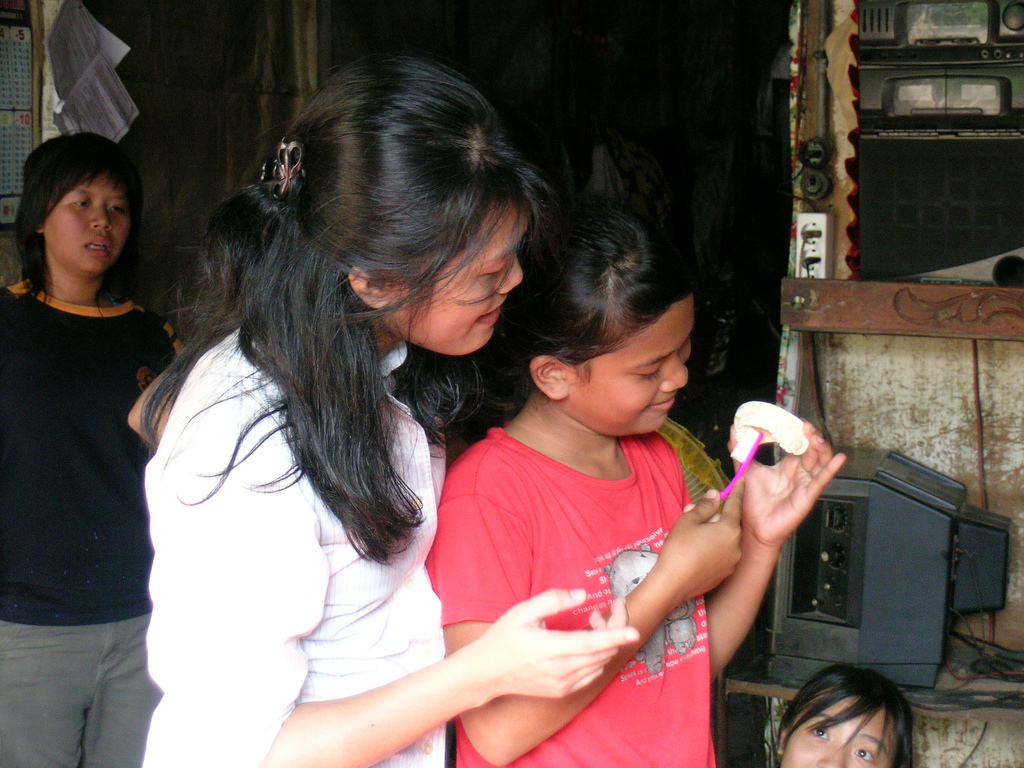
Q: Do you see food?
A: No, there is no food.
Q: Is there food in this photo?
A: No, there is no food.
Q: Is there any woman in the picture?
A: Yes, there is a woman.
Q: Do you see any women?
A: Yes, there is a woman.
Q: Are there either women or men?
A: Yes, there is a woman.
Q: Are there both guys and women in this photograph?
A: No, there is a woman but no guys.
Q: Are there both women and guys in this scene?
A: No, there is a woman but no guys.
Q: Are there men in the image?
A: No, there are no men.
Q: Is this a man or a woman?
A: This is a woman.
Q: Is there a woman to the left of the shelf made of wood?
A: Yes, there is a woman to the left of the shelf.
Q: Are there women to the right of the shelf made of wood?
A: No, the woman is to the left of the shelf.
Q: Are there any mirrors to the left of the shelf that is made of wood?
A: No, there is a woman to the left of the shelf.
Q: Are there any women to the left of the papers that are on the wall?
A: No, the woman is to the right of the papers.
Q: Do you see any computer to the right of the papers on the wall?
A: No, there is a woman to the right of the papers.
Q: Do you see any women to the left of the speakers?
A: Yes, there is a woman to the left of the speakers.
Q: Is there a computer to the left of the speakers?
A: No, there is a woman to the left of the speakers.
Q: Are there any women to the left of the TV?
A: Yes, there is a woman to the left of the TV.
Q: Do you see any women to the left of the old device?
A: Yes, there is a woman to the left of the TV.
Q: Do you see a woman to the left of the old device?
A: Yes, there is a woman to the left of the TV.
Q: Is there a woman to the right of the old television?
A: No, the woman is to the left of the TV.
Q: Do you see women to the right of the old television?
A: No, the woman is to the left of the TV.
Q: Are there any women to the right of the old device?
A: No, the woman is to the left of the TV.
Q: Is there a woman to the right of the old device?
A: No, the woman is to the left of the TV.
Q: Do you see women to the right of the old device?
A: No, the woman is to the left of the TV.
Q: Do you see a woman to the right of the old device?
A: No, the woman is to the left of the TV.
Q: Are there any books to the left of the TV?
A: No, there is a woman to the left of the TV.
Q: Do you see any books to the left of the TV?
A: No, there is a woman to the left of the TV.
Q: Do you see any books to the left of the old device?
A: No, there is a woman to the left of the TV.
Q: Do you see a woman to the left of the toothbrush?
A: Yes, there is a woman to the left of the toothbrush.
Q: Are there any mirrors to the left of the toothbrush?
A: No, there is a woman to the left of the toothbrush.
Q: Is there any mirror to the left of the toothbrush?
A: No, there is a woman to the left of the toothbrush.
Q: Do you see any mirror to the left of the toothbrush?
A: No, there is a woman to the left of the toothbrush.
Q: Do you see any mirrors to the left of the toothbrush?
A: No, there is a woman to the left of the toothbrush.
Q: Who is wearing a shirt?
A: The woman is wearing a shirt.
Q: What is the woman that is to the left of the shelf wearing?
A: The woman is wearing a shirt.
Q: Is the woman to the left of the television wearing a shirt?
A: Yes, the woman is wearing a shirt.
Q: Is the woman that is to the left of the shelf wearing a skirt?
A: No, the woman is wearing a shirt.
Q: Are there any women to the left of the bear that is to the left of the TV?
A: Yes, there is a woman to the left of the bear.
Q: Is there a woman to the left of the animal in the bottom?
A: Yes, there is a woman to the left of the bear.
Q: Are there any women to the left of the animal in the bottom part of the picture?
A: Yes, there is a woman to the left of the bear.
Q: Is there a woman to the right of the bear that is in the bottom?
A: No, the woman is to the left of the bear.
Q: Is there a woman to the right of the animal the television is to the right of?
A: No, the woman is to the left of the bear.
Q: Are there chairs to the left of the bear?
A: No, there is a woman to the left of the bear.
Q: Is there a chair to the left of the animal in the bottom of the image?
A: No, there is a woman to the left of the bear.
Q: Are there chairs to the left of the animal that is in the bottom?
A: No, there is a woman to the left of the bear.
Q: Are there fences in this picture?
A: No, there are no fences.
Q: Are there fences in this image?
A: No, there are no fences.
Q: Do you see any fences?
A: No, there are no fences.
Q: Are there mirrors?
A: No, there are no mirrors.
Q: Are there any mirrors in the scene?
A: No, there are no mirrors.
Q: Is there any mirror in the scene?
A: No, there are no mirrors.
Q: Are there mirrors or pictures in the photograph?
A: No, there are no mirrors or pictures.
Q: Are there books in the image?
A: No, there are no books.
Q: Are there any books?
A: No, there are no books.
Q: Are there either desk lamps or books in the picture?
A: No, there are no books or desk lamps.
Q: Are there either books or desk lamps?
A: No, there are no books or desk lamps.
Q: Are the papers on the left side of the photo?
A: Yes, the papers are on the left of the image.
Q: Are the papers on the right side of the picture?
A: No, the papers are on the left of the image.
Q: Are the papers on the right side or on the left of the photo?
A: The papers are on the left of the image.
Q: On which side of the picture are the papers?
A: The papers are on the left of the image.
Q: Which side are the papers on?
A: The papers are on the left of the image.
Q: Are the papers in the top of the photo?
A: Yes, the papers are in the top of the image.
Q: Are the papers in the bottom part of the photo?
A: No, the papers are in the top of the image.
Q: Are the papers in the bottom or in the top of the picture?
A: The papers are in the top of the image.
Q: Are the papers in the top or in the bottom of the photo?
A: The papers are in the top of the image.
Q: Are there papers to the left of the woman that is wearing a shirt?
A: Yes, there are papers to the left of the woman.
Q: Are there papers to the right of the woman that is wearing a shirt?
A: No, the papers are to the left of the woman.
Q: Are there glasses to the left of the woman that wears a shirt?
A: No, there are papers to the left of the woman.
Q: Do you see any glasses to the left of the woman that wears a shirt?
A: No, there are papers to the left of the woman.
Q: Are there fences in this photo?
A: No, there are no fences.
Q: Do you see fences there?
A: No, there are no fences.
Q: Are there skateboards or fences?
A: No, there are no fences or skateboards.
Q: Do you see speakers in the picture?
A: Yes, there are speakers.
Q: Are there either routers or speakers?
A: Yes, there are speakers.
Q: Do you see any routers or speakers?
A: Yes, there are speakers.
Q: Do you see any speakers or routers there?
A: Yes, there are speakers.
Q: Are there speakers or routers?
A: Yes, there are speakers.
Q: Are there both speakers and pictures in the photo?
A: No, there are speakers but no pictures.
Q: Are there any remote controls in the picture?
A: No, there are no remote controls.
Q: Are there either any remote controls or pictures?
A: No, there are no remote controls or pictures.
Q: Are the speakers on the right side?
A: Yes, the speakers are on the right of the image.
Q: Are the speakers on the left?
A: No, the speakers are on the right of the image.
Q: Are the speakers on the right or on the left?
A: The speakers are on the right of the image.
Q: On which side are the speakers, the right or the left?
A: The speakers are on the right of the image.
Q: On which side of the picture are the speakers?
A: The speakers are on the right of the image.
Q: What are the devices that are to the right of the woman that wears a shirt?
A: The devices are speakers.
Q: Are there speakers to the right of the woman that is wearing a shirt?
A: Yes, there are speakers to the right of the woman.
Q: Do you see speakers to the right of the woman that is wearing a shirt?
A: Yes, there are speakers to the right of the woman.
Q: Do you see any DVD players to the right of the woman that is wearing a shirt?
A: No, there are speakers to the right of the woman.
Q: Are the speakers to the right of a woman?
A: Yes, the speakers are to the right of a woman.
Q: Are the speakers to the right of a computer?
A: No, the speakers are to the right of a woman.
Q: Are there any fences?
A: No, there are no fences.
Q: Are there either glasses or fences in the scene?
A: No, there are no fences or glasses.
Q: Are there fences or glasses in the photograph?
A: No, there are no fences or glasses.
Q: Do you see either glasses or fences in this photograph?
A: No, there are no fences or glasses.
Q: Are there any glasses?
A: No, there are no glasses.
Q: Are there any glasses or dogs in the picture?
A: No, there are no glasses or dogs.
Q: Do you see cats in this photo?
A: No, there are no cats.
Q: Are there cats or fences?
A: No, there are no cats or fences.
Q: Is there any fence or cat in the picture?
A: No, there are no cats or fences.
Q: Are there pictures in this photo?
A: No, there are no pictures.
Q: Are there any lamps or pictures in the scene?
A: No, there are no pictures or lamps.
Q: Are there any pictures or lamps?
A: No, there are no pictures or lamps.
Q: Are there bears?
A: Yes, there is a bear.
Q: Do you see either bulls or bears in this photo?
A: Yes, there is a bear.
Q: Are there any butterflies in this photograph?
A: No, there are no butterflies.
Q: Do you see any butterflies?
A: No, there are no butterflies.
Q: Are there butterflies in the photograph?
A: No, there are no butterflies.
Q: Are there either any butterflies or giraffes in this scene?
A: No, there are no butterflies or giraffes.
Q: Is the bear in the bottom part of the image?
A: Yes, the bear is in the bottom of the image.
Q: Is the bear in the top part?
A: No, the bear is in the bottom of the image.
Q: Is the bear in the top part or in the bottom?
A: The bear is in the bottom of the image.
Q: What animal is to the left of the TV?
A: The animal is a bear.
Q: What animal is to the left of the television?
A: The animal is a bear.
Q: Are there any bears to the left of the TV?
A: Yes, there is a bear to the left of the TV.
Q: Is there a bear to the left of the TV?
A: Yes, there is a bear to the left of the TV.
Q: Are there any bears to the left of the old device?
A: Yes, there is a bear to the left of the TV.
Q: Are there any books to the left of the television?
A: No, there is a bear to the left of the television.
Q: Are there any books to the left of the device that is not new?
A: No, there is a bear to the left of the television.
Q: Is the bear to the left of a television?
A: Yes, the bear is to the left of a television.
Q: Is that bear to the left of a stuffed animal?
A: No, the bear is to the left of a television.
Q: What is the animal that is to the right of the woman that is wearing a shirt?
A: The animal is a bear.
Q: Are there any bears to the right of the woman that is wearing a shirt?
A: Yes, there is a bear to the right of the woman.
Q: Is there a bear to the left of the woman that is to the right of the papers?
A: No, the bear is to the right of the woman.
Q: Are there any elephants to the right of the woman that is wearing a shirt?
A: No, there is a bear to the right of the woman.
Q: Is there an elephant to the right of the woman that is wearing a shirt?
A: No, there is a bear to the right of the woman.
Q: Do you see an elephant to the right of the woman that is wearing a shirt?
A: No, there is a bear to the right of the woman.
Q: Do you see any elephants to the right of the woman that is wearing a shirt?
A: No, there is a bear to the right of the woman.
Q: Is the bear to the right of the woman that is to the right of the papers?
A: Yes, the bear is to the right of the woman.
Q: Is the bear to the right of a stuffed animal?
A: No, the bear is to the right of the woman.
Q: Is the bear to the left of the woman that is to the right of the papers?
A: No, the bear is to the right of the woman.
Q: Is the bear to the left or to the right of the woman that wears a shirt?
A: The bear is to the right of the woman.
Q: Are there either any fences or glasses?
A: No, there are no glasses or fences.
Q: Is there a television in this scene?
A: Yes, there is a television.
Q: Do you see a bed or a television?
A: Yes, there is a television.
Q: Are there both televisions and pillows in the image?
A: No, there is a television but no pillows.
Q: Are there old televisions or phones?
A: Yes, there is an old television.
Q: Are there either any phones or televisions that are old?
A: Yes, the television is old.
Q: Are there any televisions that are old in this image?
A: Yes, there is an old television.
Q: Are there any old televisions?
A: Yes, there is an old television.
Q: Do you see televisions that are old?
A: Yes, there is a television that is old.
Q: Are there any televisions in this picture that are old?
A: Yes, there is a television that is old.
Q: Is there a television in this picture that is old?
A: Yes, there is a television that is old.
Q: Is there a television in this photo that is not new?
A: Yes, there is a old television.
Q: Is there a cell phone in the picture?
A: No, there are no cell phones.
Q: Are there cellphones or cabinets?
A: No, there are no cellphones or cabinets.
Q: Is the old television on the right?
A: Yes, the television is on the right of the image.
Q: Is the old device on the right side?
A: Yes, the television is on the right of the image.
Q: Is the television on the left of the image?
A: No, the television is on the right of the image.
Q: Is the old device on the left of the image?
A: No, the television is on the right of the image.